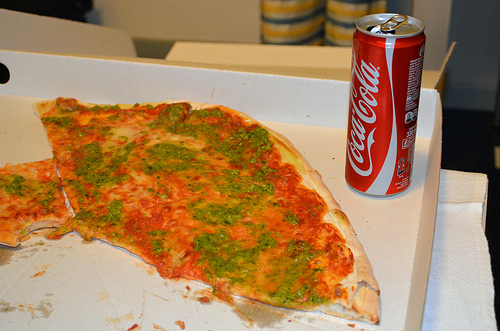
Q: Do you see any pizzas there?
A: Yes, there is a pizza.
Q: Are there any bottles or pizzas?
A: Yes, there is a pizza.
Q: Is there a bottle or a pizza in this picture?
A: Yes, there is a pizza.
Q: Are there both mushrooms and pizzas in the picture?
A: No, there is a pizza but no mushrooms.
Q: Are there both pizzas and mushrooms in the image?
A: No, there is a pizza but no mushrooms.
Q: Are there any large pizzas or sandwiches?
A: Yes, there is a large pizza.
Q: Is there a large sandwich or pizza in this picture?
A: Yes, there is a large pizza.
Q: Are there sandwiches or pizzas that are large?
A: Yes, the pizza is large.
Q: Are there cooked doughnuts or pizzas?
A: Yes, there is a cooked pizza.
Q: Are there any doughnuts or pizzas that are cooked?
A: Yes, the pizza is cooked.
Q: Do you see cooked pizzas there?
A: Yes, there is a cooked pizza.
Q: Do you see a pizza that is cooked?
A: Yes, there is a pizza that is cooked.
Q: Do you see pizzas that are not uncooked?
A: Yes, there is an cooked pizza.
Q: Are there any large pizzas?
A: Yes, there is a large pizza.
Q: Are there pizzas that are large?
A: Yes, there is a pizza that is large.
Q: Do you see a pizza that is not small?
A: Yes, there is a large pizza.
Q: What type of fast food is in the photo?
A: The fast food is a pizza.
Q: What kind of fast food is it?
A: The food is a pizza.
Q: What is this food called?
A: This is a pizza.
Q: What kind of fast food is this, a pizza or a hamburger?
A: This is a pizza.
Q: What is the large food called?
A: The food is a pizza.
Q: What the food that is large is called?
A: The food is a pizza.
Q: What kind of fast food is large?
A: The fast food is a pizza.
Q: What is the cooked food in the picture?
A: The food is a pizza.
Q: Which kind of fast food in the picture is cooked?
A: The fast food is a pizza.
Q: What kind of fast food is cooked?
A: The fast food is a pizza.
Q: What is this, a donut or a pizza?
A: This is a pizza.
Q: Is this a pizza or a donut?
A: This is a pizza.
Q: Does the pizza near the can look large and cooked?
A: Yes, the pizza is large and cooked.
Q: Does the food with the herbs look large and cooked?
A: Yes, the pizza is large and cooked.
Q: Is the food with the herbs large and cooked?
A: Yes, the pizza is large and cooked.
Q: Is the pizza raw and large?
A: No, the pizza is large but cooked.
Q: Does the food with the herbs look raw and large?
A: No, the pizza is large but cooked.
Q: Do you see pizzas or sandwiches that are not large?
A: No, there is a pizza but it is large.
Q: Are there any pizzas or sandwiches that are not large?
A: No, there is a pizza but it is large.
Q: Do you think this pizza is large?
A: Yes, the pizza is large.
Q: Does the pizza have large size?
A: Yes, the pizza is large.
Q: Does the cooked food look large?
A: Yes, the pizza is large.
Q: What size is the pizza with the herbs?
A: The pizza is large.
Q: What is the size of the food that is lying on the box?
A: The pizza is large.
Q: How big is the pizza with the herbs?
A: The pizza is large.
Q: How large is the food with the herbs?
A: The pizza is large.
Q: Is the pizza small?
A: No, the pizza is large.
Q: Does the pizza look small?
A: No, the pizza is large.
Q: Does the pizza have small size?
A: No, the pizza is large.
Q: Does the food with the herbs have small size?
A: No, the pizza is large.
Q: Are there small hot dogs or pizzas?
A: No, there is a pizza but it is large.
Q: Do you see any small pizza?
A: No, there is a pizza but it is large.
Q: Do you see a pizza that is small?
A: No, there is a pizza but it is large.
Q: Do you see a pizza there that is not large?
A: No, there is a pizza but it is large.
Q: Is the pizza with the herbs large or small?
A: The pizza is large.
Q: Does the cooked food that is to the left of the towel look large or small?
A: The pizza is large.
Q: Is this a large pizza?
A: Yes, this is a large pizza.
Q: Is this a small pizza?
A: No, this is a large pizza.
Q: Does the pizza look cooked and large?
A: Yes, the pizza is cooked and large.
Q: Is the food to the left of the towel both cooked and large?
A: Yes, the pizza is cooked and large.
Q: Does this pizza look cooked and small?
A: No, the pizza is cooked but large.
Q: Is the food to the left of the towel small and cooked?
A: No, the pizza is cooked but large.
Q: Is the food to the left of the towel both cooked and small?
A: No, the pizza is cooked but large.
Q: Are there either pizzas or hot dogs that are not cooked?
A: No, there is a pizza but it is cooked.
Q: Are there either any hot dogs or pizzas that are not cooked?
A: No, there is a pizza but it is cooked.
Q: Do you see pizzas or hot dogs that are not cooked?
A: No, there is a pizza but it is cooked.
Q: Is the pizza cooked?
A: Yes, the pizza is cooked.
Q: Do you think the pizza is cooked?
A: Yes, the pizza is cooked.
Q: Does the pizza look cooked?
A: Yes, the pizza is cooked.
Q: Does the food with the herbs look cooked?
A: Yes, the pizza is cooked.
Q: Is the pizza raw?
A: No, the pizza is cooked.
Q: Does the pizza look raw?
A: No, the pizza is cooked.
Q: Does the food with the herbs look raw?
A: No, the pizza is cooked.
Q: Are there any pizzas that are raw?
A: No, there is a pizza but it is cooked.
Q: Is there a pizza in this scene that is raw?
A: No, there is a pizza but it is cooked.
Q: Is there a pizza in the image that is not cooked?
A: No, there is a pizza but it is cooked.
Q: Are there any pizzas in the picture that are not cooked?
A: No, there is a pizza but it is cooked.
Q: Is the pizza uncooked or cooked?
A: The pizza is cooked.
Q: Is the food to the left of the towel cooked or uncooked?
A: The pizza is cooked.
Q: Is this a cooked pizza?
A: Yes, this is a cooked pizza.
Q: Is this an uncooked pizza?
A: No, this is a cooked pizza.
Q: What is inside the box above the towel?
A: The pizza is inside the box.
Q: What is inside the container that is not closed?
A: The pizza is inside the box.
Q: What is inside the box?
A: The pizza is inside the box.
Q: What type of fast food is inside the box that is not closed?
A: The food is a pizza.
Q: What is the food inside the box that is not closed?
A: The food is a pizza.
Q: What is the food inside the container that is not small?
A: The food is a pizza.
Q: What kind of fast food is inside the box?
A: The food is a pizza.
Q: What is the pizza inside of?
A: The pizza is inside the box.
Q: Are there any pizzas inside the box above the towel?
A: Yes, there is a pizza inside the box.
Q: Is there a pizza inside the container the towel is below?
A: Yes, there is a pizza inside the box.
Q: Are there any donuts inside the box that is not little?
A: No, there is a pizza inside the box.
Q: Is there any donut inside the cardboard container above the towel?
A: No, there is a pizza inside the box.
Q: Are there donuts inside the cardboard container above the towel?
A: No, there is a pizza inside the box.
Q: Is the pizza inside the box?
A: Yes, the pizza is inside the box.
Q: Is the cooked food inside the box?
A: Yes, the pizza is inside the box.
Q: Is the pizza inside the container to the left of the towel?
A: Yes, the pizza is inside the box.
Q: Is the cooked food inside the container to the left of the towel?
A: Yes, the pizza is inside the box.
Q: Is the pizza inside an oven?
A: No, the pizza is inside the box.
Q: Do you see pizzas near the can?
A: Yes, there is a pizza near the can.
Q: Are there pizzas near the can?
A: Yes, there is a pizza near the can.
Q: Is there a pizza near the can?
A: Yes, there is a pizza near the can.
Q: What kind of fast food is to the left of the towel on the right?
A: The food is a pizza.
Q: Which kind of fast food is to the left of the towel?
A: The food is a pizza.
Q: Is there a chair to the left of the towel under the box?
A: No, there is a pizza to the left of the towel.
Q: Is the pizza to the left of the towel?
A: Yes, the pizza is to the left of the towel.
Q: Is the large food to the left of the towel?
A: Yes, the pizza is to the left of the towel.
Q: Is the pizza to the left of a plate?
A: No, the pizza is to the left of the towel.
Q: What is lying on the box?
A: The pizza is lying on the box.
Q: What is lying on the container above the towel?
A: The pizza is lying on the box.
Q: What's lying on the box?
A: The pizza is lying on the box.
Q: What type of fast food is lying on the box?
A: The food is a pizza.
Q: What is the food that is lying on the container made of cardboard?
A: The food is a pizza.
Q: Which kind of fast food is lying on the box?
A: The food is a pizza.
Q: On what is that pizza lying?
A: The pizza is lying on the box.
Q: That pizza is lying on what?
A: The pizza is lying on the box.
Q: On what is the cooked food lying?
A: The pizza is lying on the box.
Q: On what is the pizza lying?
A: The pizza is lying on the box.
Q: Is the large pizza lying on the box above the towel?
A: Yes, the pizza is lying on the box.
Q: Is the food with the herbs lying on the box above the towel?
A: Yes, the pizza is lying on the box.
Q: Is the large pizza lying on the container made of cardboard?
A: Yes, the pizza is lying on the box.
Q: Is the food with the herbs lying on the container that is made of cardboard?
A: Yes, the pizza is lying on the box.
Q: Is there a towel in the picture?
A: Yes, there is a towel.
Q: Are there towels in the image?
A: Yes, there is a towel.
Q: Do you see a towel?
A: Yes, there is a towel.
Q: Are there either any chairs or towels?
A: Yes, there is a towel.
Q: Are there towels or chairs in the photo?
A: Yes, there is a towel.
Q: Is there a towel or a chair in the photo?
A: Yes, there is a towel.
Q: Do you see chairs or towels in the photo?
A: Yes, there is a towel.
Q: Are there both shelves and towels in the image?
A: No, there is a towel but no shelves.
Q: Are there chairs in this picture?
A: No, there are no chairs.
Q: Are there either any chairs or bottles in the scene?
A: No, there are no chairs or bottles.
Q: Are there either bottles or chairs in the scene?
A: No, there are no chairs or bottles.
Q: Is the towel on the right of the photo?
A: Yes, the towel is on the right of the image.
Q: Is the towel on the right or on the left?
A: The towel is on the right of the image.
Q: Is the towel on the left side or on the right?
A: The towel is on the right of the image.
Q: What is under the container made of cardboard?
A: The towel is under the box.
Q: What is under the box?
A: The towel is under the box.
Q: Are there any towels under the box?
A: Yes, there is a towel under the box.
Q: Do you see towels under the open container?
A: Yes, there is a towel under the box.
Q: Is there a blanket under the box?
A: No, there is a towel under the box.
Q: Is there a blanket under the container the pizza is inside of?
A: No, there is a towel under the box.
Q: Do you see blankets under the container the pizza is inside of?
A: No, there is a towel under the box.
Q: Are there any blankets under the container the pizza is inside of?
A: No, there is a towel under the box.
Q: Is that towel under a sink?
A: No, the towel is under a box.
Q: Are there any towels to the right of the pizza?
A: Yes, there is a towel to the right of the pizza.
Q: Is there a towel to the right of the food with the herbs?
A: Yes, there is a towel to the right of the pizza.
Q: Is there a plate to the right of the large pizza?
A: No, there is a towel to the right of the pizza.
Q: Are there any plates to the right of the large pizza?
A: No, there is a towel to the right of the pizza.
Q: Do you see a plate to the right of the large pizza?
A: No, there is a towel to the right of the pizza.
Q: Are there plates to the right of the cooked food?
A: No, there is a towel to the right of the pizza.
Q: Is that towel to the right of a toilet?
A: No, the towel is to the right of the pizza.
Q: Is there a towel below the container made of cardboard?
A: Yes, there is a towel below the box.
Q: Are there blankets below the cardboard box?
A: No, there is a towel below the box.